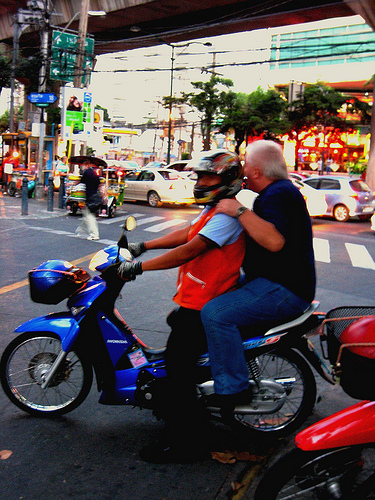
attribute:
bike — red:
[10, 200, 368, 392]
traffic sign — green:
[46, 31, 100, 79]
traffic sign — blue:
[27, 93, 57, 102]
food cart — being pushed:
[61, 153, 133, 221]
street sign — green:
[47, 66, 92, 87]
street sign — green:
[49, 50, 98, 69]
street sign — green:
[51, 27, 95, 52]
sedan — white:
[122, 151, 208, 232]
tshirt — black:
[246, 179, 318, 299]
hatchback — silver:
[298, 172, 371, 220]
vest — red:
[170, 208, 244, 310]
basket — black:
[35, 248, 87, 305]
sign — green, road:
[50, 32, 86, 93]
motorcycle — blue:
[0, 216, 336, 439]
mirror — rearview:
[115, 212, 143, 238]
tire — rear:
[220, 344, 318, 444]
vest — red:
[174, 207, 246, 315]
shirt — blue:
[182, 200, 241, 250]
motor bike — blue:
[9, 218, 317, 443]